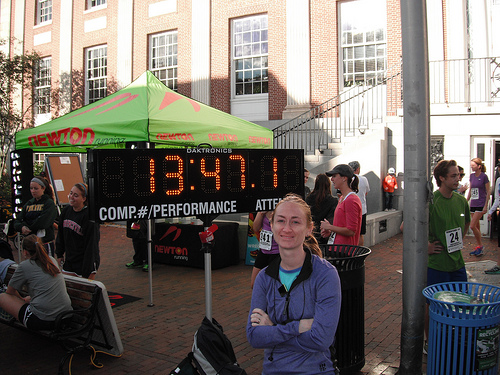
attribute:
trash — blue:
[418, 279, 499, 374]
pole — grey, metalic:
[400, 0, 430, 374]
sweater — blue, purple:
[247, 260, 341, 374]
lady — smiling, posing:
[3, 233, 75, 337]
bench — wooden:
[6, 262, 113, 374]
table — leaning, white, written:
[71, 269, 122, 358]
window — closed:
[228, 14, 269, 99]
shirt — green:
[422, 189, 469, 271]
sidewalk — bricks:
[119, 266, 260, 370]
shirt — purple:
[256, 202, 280, 256]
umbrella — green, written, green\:
[16, 67, 275, 150]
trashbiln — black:
[309, 239, 374, 374]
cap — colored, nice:
[325, 163, 351, 176]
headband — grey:
[34, 177, 45, 194]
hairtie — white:
[34, 242, 39, 247]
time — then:
[145, 152, 281, 197]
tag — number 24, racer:
[446, 228, 465, 252]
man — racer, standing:
[422, 156, 476, 349]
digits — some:
[144, 152, 186, 200]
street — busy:
[14, 48, 491, 370]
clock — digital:
[91, 135, 301, 228]